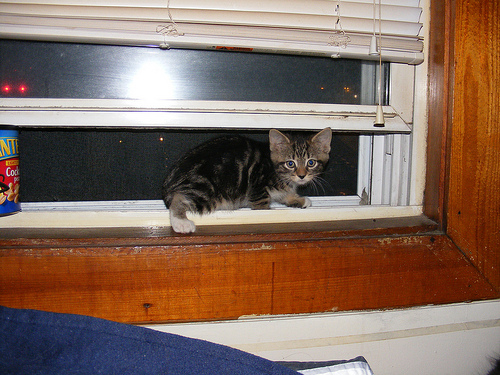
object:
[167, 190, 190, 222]
leg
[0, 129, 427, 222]
under window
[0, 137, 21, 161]
brand name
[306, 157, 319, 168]
eyes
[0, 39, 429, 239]
window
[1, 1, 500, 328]
wood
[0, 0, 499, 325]
frame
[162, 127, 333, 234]
cat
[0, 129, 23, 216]
can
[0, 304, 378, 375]
bedding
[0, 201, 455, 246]
sill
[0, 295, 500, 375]
ground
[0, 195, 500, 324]
cat window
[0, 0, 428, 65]
blinds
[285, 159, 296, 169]
eye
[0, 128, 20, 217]
nutcan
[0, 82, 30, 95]
lights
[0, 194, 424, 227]
windowsill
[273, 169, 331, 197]
whiskers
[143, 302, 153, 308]
knot